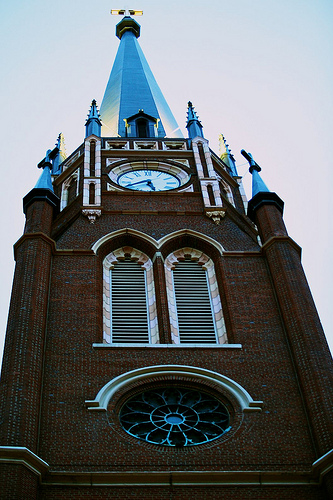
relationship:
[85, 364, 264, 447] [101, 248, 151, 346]
window below window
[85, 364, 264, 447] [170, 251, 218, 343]
window below window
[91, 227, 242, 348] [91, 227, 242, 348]
window with window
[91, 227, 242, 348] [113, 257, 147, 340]
window with slats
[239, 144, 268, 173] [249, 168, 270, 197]
cross sits atop column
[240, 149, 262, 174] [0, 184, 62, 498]
cross sits atop column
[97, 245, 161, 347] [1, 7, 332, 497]
window on building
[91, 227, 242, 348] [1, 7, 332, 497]
window on building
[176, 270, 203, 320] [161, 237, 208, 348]
slats on window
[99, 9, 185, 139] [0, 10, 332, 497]
steeple on tower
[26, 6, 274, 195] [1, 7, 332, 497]
roof on building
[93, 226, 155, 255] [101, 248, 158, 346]
dormer over window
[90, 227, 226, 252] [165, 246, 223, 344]
dormer over window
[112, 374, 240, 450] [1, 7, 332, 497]
window on building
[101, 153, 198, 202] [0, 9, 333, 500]
clock in front of building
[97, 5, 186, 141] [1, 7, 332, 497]
steeple on top of building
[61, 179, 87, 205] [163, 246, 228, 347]
window surrounded by tile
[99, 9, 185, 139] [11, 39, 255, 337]
steeple on building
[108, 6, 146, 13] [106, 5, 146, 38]
top of spire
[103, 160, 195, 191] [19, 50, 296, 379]
clock attached to tower